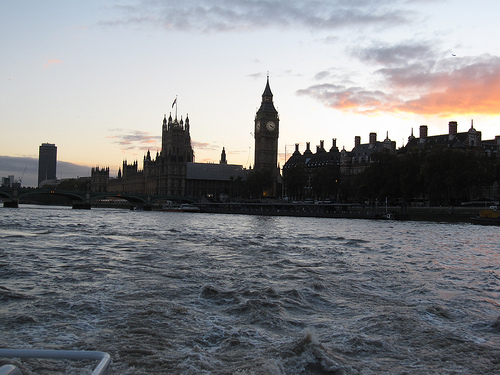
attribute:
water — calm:
[0, 202, 499, 374]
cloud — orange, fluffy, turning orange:
[296, 40, 499, 116]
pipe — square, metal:
[0, 345, 114, 374]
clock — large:
[265, 118, 278, 133]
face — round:
[265, 120, 278, 134]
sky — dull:
[1, 1, 498, 188]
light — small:
[260, 191, 269, 199]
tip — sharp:
[265, 72, 272, 83]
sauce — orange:
[479, 206, 499, 220]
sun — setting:
[77, 160, 122, 174]